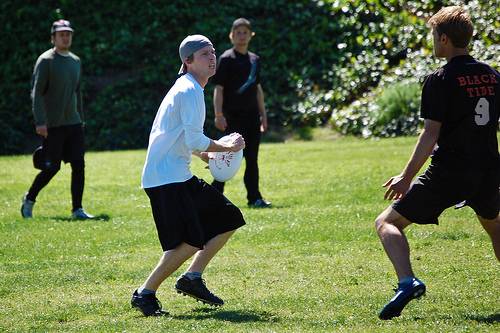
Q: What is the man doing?
A: Football.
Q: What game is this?
A: Frisbee.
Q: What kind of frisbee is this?
A: White frisbee.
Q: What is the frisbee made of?
A: Plastic.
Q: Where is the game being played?
A: Green field.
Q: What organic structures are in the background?
A: Brush and foliage.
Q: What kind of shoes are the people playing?
A: Cleats.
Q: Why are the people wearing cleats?
A: To better grip the ground when running.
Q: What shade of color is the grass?
A: Green.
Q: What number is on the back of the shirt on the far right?
A: 9.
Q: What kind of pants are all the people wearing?
A: Shorts.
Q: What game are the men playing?
A: Frisbee.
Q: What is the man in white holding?
A: A frisbee.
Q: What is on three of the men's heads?
A: Hats.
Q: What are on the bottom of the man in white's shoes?
A: Spikes.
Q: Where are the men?
A: In a field.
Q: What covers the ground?
A: Grass.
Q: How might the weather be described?
A: Sunny.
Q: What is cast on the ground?
A: A shadow.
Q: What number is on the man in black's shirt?
A: 9.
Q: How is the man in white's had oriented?
A: Backward.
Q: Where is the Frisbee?
A: In the hands of the man in white.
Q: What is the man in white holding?
A: A Frisbee.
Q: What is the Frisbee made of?
A: Plastic.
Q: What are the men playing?
A: Frisbee.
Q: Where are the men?
A: On the field.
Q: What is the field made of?
A: Grass.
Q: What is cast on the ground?
A: Shadows.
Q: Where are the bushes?
A: Behind the men.